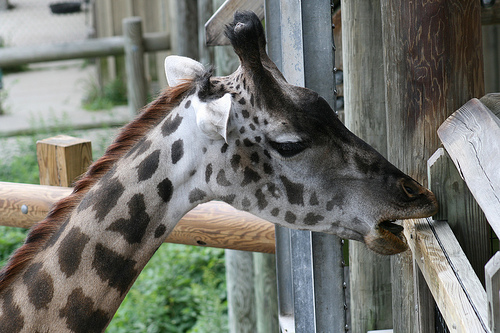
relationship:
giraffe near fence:
[0, 10, 436, 333] [276, 15, 490, 326]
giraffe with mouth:
[0, 10, 436, 333] [361, 190, 441, 264]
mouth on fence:
[361, 190, 441, 264] [323, 87, 483, 329]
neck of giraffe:
[10, 159, 176, 331] [33, 60, 428, 330]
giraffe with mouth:
[0, 10, 436, 333] [362, 174, 447, 258]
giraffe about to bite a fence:
[22, 22, 493, 325] [402, 93, 500, 333]